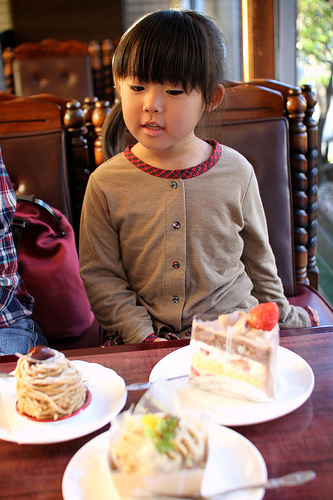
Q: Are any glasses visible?
A: No, there are no glasses.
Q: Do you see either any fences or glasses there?
A: No, there are no glasses or fences.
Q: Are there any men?
A: No, there are no men.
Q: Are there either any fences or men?
A: No, there are no men or fences.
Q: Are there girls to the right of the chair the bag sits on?
A: Yes, there is a girl to the right of the chair.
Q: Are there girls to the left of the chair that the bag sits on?
A: No, the girl is to the right of the chair.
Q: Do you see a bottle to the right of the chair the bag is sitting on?
A: No, there is a girl to the right of the chair.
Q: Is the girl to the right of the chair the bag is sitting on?
A: Yes, the girl is to the right of the chair.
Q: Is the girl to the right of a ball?
A: No, the girl is to the right of the chair.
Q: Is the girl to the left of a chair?
A: No, the girl is to the right of a chair.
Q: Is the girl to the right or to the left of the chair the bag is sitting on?
A: The girl is to the right of the chair.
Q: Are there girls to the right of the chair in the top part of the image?
A: Yes, there is a girl to the right of the chair.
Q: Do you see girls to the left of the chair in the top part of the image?
A: No, the girl is to the right of the chair.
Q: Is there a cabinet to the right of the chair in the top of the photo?
A: No, there is a girl to the right of the chair.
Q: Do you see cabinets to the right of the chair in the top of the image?
A: No, there is a girl to the right of the chair.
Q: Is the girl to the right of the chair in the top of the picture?
A: Yes, the girl is to the right of the chair.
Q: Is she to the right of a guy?
A: No, the girl is to the right of the chair.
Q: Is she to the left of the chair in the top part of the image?
A: No, the girl is to the right of the chair.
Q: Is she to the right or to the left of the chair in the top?
A: The girl is to the right of the chair.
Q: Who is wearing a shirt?
A: The girl is wearing a shirt.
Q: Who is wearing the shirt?
A: The girl is wearing a shirt.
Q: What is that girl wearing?
A: The girl is wearing a shirt.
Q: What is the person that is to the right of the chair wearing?
A: The girl is wearing a shirt.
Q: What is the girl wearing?
A: The girl is wearing a shirt.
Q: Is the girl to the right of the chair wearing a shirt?
A: Yes, the girl is wearing a shirt.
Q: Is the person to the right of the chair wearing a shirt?
A: Yes, the girl is wearing a shirt.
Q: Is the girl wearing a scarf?
A: No, the girl is wearing a shirt.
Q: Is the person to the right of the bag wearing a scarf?
A: No, the girl is wearing a shirt.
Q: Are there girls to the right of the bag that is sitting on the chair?
A: Yes, there is a girl to the right of the bag.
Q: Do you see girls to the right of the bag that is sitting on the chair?
A: Yes, there is a girl to the right of the bag.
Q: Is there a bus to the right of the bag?
A: No, there is a girl to the right of the bag.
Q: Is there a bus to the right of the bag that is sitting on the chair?
A: No, there is a girl to the right of the bag.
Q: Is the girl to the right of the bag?
A: Yes, the girl is to the right of the bag.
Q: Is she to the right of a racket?
A: No, the girl is to the right of the bag.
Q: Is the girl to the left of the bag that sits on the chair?
A: No, the girl is to the right of the bag.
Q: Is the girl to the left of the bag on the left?
A: No, the girl is to the right of the bag.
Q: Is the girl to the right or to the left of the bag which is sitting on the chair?
A: The girl is to the right of the bag.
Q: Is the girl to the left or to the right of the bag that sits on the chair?
A: The girl is to the right of the bag.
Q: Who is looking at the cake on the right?
A: The girl is looking at the cake.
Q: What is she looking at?
A: The girl is looking at the cake.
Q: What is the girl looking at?
A: The girl is looking at the cake.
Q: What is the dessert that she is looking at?
A: The dessert is a cake.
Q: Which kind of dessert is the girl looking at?
A: The girl is looking at the cake.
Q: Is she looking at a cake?
A: Yes, the girl is looking at a cake.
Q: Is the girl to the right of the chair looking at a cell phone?
A: No, the girl is looking at a cake.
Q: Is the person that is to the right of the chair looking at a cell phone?
A: No, the girl is looking at a cake.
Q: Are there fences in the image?
A: No, there are no fences.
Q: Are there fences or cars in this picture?
A: No, there are no fences or cars.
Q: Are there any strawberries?
A: Yes, there is a strawberry.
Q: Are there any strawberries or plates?
A: Yes, there is a strawberry.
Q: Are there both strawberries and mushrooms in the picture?
A: No, there is a strawberry but no mushrooms.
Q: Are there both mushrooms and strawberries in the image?
A: No, there is a strawberry but no mushrooms.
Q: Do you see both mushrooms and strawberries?
A: No, there is a strawberry but no mushrooms.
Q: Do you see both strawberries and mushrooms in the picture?
A: No, there is a strawberry but no mushrooms.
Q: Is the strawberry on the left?
A: No, the strawberry is on the right of the image.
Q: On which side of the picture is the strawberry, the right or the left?
A: The strawberry is on the right of the image.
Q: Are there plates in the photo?
A: Yes, there is a plate.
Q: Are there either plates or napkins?
A: Yes, there is a plate.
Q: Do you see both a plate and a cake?
A: Yes, there are both a plate and a cake.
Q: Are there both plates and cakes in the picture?
A: Yes, there are both a plate and a cake.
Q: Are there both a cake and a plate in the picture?
A: Yes, there are both a plate and a cake.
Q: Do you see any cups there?
A: No, there are no cups.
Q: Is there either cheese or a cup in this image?
A: No, there are no cups or cheese.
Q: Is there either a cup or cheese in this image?
A: No, there are no cups or cheese.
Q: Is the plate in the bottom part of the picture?
A: Yes, the plate is in the bottom of the image.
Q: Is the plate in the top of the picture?
A: No, the plate is in the bottom of the image.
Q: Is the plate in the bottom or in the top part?
A: The plate is in the bottom of the image.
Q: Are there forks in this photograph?
A: Yes, there is a fork.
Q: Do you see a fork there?
A: Yes, there is a fork.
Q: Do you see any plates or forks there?
A: Yes, there is a fork.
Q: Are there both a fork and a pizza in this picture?
A: No, there is a fork but no pizzas.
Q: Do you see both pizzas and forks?
A: No, there is a fork but no pizzas.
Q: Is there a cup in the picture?
A: No, there are no cups.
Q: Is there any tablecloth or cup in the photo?
A: No, there are no cups or tablecloths.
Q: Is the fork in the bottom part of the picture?
A: Yes, the fork is in the bottom of the image.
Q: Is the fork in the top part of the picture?
A: No, the fork is in the bottom of the image.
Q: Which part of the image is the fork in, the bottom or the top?
A: The fork is in the bottom of the image.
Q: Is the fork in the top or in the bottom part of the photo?
A: The fork is in the bottom of the image.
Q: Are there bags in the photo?
A: Yes, there is a bag.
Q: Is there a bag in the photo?
A: Yes, there is a bag.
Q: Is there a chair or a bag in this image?
A: Yes, there is a bag.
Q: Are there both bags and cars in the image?
A: No, there is a bag but no cars.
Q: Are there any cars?
A: No, there are no cars.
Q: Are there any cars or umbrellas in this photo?
A: No, there are no cars or umbrellas.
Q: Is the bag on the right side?
A: No, the bag is on the left of the image.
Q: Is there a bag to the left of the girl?
A: Yes, there is a bag to the left of the girl.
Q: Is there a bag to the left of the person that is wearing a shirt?
A: Yes, there is a bag to the left of the girl.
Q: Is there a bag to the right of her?
A: No, the bag is to the left of the girl.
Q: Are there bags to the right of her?
A: No, the bag is to the left of the girl.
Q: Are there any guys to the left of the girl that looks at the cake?
A: No, there is a bag to the left of the girl.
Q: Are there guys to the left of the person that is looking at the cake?
A: No, there is a bag to the left of the girl.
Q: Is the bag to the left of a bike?
A: No, the bag is to the left of the girl.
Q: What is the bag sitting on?
A: The bag is sitting on the chair.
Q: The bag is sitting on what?
A: The bag is sitting on the chair.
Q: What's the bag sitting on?
A: The bag is sitting on the chair.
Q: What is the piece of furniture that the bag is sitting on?
A: The piece of furniture is a chair.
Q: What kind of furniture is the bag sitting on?
A: The bag is sitting on the chair.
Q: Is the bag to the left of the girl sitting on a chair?
A: Yes, the bag is sitting on a chair.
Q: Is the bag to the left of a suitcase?
A: No, the bag is to the left of a chair.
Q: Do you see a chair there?
A: Yes, there is a chair.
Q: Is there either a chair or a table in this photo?
A: Yes, there is a chair.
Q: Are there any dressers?
A: No, there are no dressers.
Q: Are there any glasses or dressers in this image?
A: No, there are no dressers or glasses.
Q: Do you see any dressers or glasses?
A: No, there are no dressers or glasses.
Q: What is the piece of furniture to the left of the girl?
A: The piece of furniture is a chair.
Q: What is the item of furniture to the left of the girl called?
A: The piece of furniture is a chair.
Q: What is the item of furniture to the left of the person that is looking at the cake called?
A: The piece of furniture is a chair.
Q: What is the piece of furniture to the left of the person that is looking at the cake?
A: The piece of furniture is a chair.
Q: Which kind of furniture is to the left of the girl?
A: The piece of furniture is a chair.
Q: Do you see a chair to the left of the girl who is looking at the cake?
A: Yes, there is a chair to the left of the girl.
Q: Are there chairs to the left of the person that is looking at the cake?
A: Yes, there is a chair to the left of the girl.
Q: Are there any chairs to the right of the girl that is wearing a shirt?
A: No, the chair is to the left of the girl.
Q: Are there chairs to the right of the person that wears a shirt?
A: No, the chair is to the left of the girl.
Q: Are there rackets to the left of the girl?
A: No, there is a chair to the left of the girl.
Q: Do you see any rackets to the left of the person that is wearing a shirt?
A: No, there is a chair to the left of the girl.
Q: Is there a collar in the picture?
A: Yes, there is a collar.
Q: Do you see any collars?
A: Yes, there is a collar.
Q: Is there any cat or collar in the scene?
A: Yes, there is a collar.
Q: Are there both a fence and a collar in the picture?
A: No, there is a collar but no fences.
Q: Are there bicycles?
A: No, there are no bicycles.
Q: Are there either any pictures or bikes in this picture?
A: No, there are no bikes or pictures.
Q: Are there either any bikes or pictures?
A: No, there are no bikes or pictures.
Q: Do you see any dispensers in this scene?
A: No, there are no dispensers.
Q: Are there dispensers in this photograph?
A: No, there are no dispensers.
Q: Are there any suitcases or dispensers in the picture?
A: No, there are no dispensers or suitcases.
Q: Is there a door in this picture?
A: Yes, there is a door.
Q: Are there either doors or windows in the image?
A: Yes, there is a door.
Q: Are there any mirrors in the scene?
A: No, there are no mirrors.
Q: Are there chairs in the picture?
A: Yes, there is a chair.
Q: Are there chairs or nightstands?
A: Yes, there is a chair.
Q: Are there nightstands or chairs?
A: Yes, there is a chair.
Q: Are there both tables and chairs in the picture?
A: Yes, there are both a chair and a table.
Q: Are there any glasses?
A: No, there are no glasses.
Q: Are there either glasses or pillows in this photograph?
A: No, there are no glasses or pillows.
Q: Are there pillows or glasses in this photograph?
A: No, there are no glasses or pillows.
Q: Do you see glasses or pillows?
A: No, there are no glasses or pillows.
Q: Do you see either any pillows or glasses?
A: No, there are no glasses or pillows.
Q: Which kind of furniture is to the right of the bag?
A: The piece of furniture is a chair.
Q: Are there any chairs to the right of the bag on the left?
A: Yes, there is a chair to the right of the bag.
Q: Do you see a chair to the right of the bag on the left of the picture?
A: Yes, there is a chair to the right of the bag.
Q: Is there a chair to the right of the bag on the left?
A: Yes, there is a chair to the right of the bag.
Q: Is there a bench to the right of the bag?
A: No, there is a chair to the right of the bag.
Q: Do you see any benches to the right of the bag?
A: No, there is a chair to the right of the bag.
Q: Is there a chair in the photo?
A: Yes, there is a chair.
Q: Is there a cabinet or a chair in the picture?
A: Yes, there is a chair.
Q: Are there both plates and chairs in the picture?
A: Yes, there are both a chair and a plate.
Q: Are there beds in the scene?
A: No, there are no beds.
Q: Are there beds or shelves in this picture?
A: No, there are no beds or shelves.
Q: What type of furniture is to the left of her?
A: The piece of furniture is a chair.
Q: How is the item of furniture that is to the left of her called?
A: The piece of furniture is a chair.